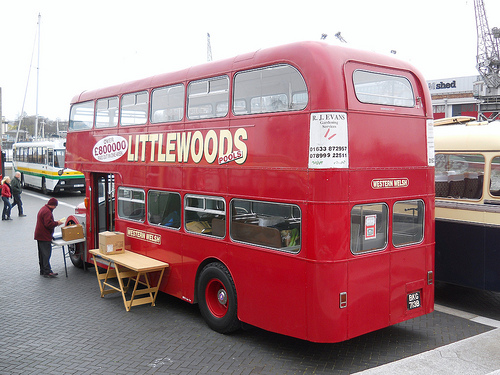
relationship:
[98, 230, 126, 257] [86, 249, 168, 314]
box on table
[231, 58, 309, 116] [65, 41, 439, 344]
window on bus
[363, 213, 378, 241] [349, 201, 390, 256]
sign on window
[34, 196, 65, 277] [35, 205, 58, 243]
man wearing coat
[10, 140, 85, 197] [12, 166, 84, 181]
bus has stripes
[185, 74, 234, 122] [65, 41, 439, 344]
window of bus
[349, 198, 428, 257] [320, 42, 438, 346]
windows on back of  bus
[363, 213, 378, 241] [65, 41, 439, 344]
advertisement on bus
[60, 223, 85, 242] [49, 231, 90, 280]
box on table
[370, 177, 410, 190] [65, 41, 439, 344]
logo on bus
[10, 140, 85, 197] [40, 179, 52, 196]
bus has tire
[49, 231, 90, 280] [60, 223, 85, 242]
table with box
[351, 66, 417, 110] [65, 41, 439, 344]
window on bus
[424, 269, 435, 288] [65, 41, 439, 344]
tail light on bus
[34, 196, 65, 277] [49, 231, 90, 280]
man by table